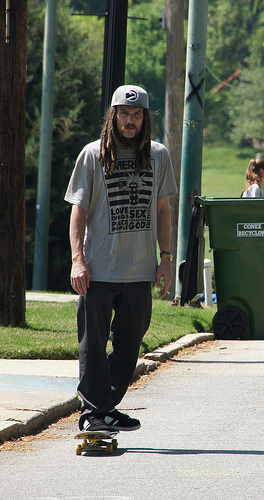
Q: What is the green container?
A: Trash can.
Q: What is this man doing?
A: Riding a skateboard.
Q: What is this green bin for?
A: Trash recycling.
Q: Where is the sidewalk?
A: Near the street on left.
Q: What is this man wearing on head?
A: Gray hat.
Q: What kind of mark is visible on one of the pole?
A: Cross mark.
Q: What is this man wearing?
A: Gray shirt with black writing on front.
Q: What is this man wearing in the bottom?
A: Black athletic pants.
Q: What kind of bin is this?
A: Recycling.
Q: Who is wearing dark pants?
A: A male skateboarder.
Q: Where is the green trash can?
A: The street.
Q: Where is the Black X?
A: On the green pole.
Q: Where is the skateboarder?
A: On a gray street.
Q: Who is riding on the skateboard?
A: The man.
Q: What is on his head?
A: A hat.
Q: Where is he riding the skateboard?
A: On the street.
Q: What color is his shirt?
A: Gray.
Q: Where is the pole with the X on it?
A: Behind the man.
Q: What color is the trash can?
A: Green.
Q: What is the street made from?
A: Concrete.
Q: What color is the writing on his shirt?
A: Black.